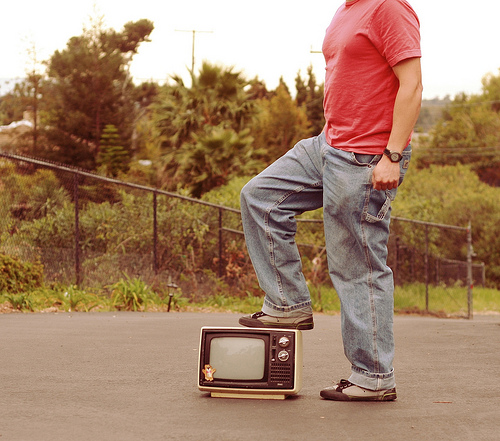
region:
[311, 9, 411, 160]
the shirt is red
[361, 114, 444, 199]
man is wearing a watch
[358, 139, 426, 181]
man is wearing a watch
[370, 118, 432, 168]
man is wearing a watch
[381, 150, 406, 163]
black watch on man's left wrist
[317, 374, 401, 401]
black shoe on left foot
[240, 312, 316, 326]
black shoe on right foot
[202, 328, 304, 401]
small television on ground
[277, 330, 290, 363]
small knobs on the televison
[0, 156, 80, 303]
black fence surrounding the man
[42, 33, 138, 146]
dark green pine trees behind fence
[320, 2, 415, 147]
red t-shirt worn by man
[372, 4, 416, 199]
the man's left arm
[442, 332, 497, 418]
cement pavement on ground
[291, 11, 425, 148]
man has red shirt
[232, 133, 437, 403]
man has blue jeans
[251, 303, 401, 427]
black and grey shoes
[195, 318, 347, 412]
man stands on tv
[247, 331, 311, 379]
grey dials on tv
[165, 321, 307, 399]
tv on grey concrete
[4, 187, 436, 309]
black chain link fence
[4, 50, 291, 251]
green trees behind fence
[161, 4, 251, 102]
telephone poles behind trees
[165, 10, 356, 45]
sky is bright grey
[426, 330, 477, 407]
black asphalt surface of the ground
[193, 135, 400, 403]
a man standing on a small tv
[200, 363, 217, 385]
a small bear picture on the tv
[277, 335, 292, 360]
grey dials of the tv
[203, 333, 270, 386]
small grey screen of the tv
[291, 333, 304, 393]
white case of the tv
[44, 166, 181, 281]
black chain link fence next to the road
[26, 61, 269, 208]
many green trees growing in the distance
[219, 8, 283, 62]
cloudy white skies over the scene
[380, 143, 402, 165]
black watch on the man's wrist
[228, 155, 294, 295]
this is the leg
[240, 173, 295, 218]
then knee is bent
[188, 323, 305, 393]
this is a tv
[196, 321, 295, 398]
the tv is small in size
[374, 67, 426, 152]
this is the hand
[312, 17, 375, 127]
the t shirt is red in color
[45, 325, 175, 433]
this is the road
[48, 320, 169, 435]
the road is tarmacked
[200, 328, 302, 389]
the tv is old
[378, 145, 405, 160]
this is a wrist watch